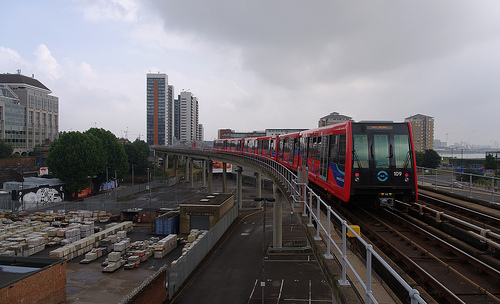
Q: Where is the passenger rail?
A: Over the city.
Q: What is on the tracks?
A: A train.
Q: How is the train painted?
A: In red and blue.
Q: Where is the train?
A: A bridge.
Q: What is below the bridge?
A: Car Park.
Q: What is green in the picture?
A: Trees.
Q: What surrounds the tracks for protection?
A: A guardrail.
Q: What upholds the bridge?
A: Cement pillars.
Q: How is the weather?
A: Overcast.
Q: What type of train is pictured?
A: Passenger.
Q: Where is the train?
A: On bridge.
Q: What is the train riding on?
A: Tracks.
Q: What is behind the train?
A: City.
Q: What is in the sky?
A: Clouds.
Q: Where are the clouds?
A: Sky.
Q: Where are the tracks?
A: On bridge.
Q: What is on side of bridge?
A: Railing.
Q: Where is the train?
A: On the track.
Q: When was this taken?
A: Daytime.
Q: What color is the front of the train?
A: Black.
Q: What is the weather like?
A: Partly cloudy.